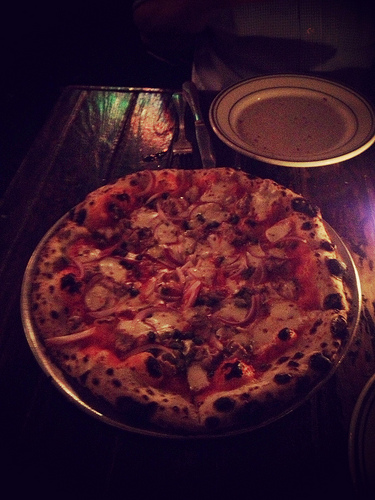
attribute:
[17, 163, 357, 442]
pizza — slice, sitting, sliced, baked, cooked, round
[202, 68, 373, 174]
plate — porcelain, round, white, empty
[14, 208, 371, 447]
platter — silver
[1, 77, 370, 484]
table — wooden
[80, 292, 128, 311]
cheese — melted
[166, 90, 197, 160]
fork — metal, silver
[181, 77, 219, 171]
knife — metal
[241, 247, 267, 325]
onions — sliced, purple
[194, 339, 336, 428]
crust — burned